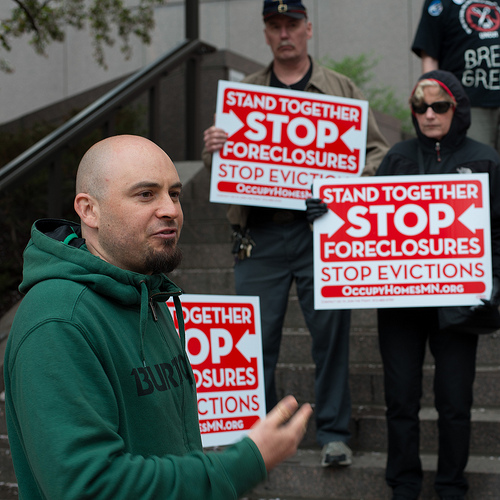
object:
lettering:
[320, 280, 486, 298]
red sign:
[208, 78, 370, 211]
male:
[0, 131, 314, 499]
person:
[2, 134, 316, 499]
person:
[375, 69, 500, 499]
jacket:
[373, 68, 499, 337]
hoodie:
[0, 215, 270, 499]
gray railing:
[61, 57, 184, 128]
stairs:
[0, 157, 499, 499]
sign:
[165, 294, 267, 450]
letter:
[346, 203, 371, 237]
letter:
[368, 203, 396, 236]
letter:
[394, 203, 428, 236]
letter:
[429, 202, 456, 235]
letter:
[244, 110, 268, 142]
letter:
[264, 112, 289, 144]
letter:
[286, 116, 316, 147]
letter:
[316, 119, 339, 149]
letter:
[209, 327, 234, 364]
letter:
[184, 327, 210, 366]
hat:
[261, 0, 306, 21]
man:
[202, 0, 391, 469]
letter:
[323, 188, 335, 204]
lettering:
[345, 203, 455, 238]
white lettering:
[225, 91, 359, 124]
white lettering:
[324, 236, 481, 259]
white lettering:
[168, 306, 255, 388]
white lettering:
[341, 284, 464, 296]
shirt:
[408, 0, 499, 112]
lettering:
[323, 237, 482, 259]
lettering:
[189, 306, 252, 324]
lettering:
[223, 139, 357, 171]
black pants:
[375, 306, 480, 499]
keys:
[228, 228, 257, 263]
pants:
[230, 208, 360, 443]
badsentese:
[372, 72, 483, 342]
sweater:
[39, 269, 169, 409]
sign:
[311, 172, 493, 311]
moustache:
[276, 36, 296, 51]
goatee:
[144, 239, 184, 275]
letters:
[130, 354, 190, 398]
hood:
[408, 69, 472, 148]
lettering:
[322, 183, 479, 204]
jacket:
[199, 55, 391, 239]